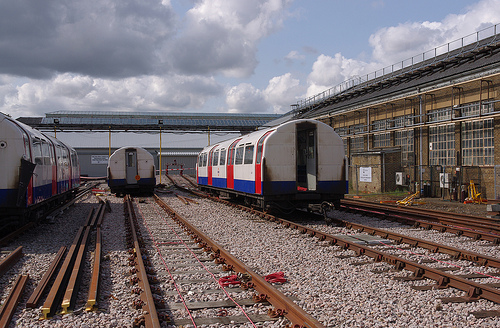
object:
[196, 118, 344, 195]
train car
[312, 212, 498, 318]
railroad tracks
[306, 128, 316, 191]
door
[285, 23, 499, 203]
building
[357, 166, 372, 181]
sign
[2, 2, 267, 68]
sky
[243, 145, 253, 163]
window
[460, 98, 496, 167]
windows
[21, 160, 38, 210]
railing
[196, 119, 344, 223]
train